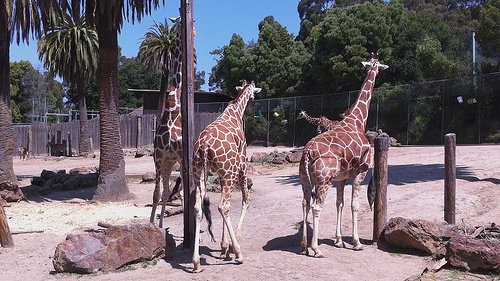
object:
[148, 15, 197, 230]
giraffe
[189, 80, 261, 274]
giraffe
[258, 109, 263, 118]
street sign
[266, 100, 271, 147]
pole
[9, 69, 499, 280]
cage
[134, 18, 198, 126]
palm trees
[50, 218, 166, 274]
rock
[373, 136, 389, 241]
post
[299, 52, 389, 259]
giraffe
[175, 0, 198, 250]
pole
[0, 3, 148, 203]
palm tree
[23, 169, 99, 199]
shadow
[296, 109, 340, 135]
giraffe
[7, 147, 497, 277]
ground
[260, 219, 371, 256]
shadow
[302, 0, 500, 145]
oak tree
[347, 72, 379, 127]
neck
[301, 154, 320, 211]
tail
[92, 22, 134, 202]
trunk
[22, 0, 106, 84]
leaves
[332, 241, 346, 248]
hoof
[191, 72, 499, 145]
fence